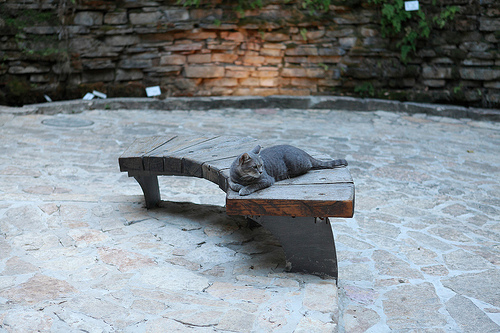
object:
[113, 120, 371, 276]
platform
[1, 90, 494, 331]
ground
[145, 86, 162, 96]
sign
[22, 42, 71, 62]
plants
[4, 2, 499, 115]
wall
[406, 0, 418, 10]
sign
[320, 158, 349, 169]
tail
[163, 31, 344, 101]
patch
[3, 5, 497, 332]
picture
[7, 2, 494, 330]
courtyard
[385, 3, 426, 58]
ivy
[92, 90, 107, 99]
paper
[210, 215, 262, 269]
shadow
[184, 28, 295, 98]
light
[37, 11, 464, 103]
wall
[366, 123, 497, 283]
walkway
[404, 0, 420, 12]
paper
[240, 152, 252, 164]
ears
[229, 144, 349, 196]
cat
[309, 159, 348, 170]
stripes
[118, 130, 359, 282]
bench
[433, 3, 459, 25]
plants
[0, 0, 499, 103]
fence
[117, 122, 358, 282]
table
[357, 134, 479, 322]
street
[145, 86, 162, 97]
paper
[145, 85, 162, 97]
pieces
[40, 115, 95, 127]
cover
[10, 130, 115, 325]
street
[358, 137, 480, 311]
driveway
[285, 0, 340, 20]
vegetation